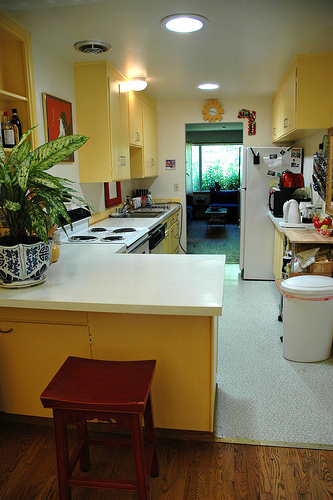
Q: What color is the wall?
A: Yellow.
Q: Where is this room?
A: Kitchen.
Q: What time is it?
A: Day time.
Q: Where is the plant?
A: The counter.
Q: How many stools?
A: One.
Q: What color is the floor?
A: White.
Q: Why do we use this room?
A: Food.